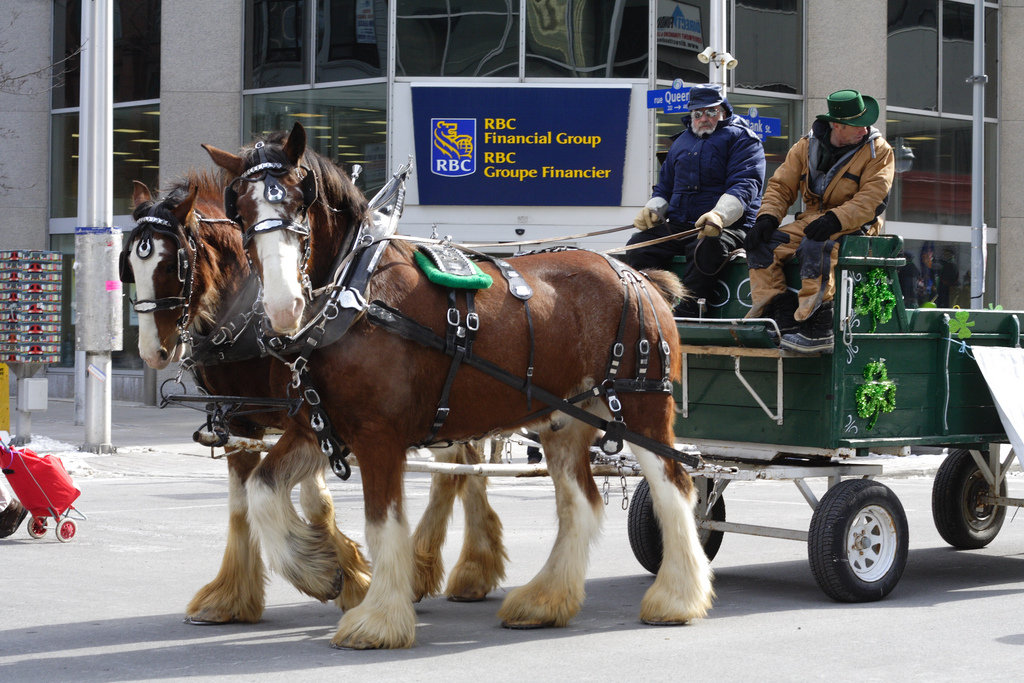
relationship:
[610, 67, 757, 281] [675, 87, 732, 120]
man wearing hat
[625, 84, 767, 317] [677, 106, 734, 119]
man wearing sunglasses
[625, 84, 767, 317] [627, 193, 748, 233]
man wearing gloves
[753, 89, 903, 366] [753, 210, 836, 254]
man wearing gloves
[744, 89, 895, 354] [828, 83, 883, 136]
man wearing hat